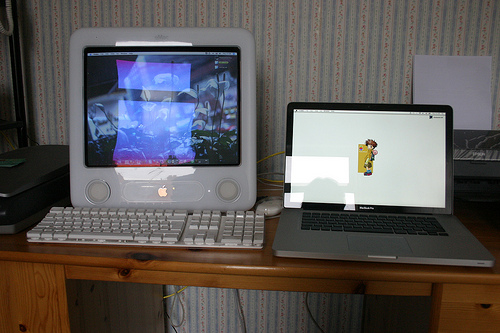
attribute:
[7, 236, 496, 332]
desk — wooden, brown, wood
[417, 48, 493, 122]
paper — white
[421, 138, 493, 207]
printer — gray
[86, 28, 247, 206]
monitor — white, apple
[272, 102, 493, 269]
laptop — silver, black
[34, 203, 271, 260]
keyboard — white, grey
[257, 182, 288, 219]
mouse — white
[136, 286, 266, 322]
cords — hanging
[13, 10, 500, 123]
wallpaper — striped, blue, floral, white, red, stripped, printed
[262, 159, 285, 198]
cord — white